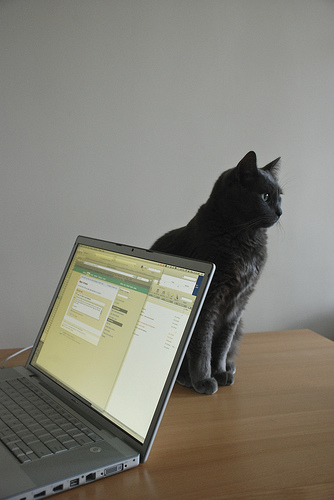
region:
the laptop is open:
[38, 257, 175, 489]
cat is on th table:
[176, 173, 291, 368]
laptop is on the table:
[48, 251, 205, 468]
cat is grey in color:
[194, 105, 275, 401]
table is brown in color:
[235, 372, 298, 439]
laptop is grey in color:
[23, 354, 127, 498]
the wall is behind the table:
[12, 71, 245, 331]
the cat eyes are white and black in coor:
[253, 187, 300, 207]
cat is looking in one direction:
[193, 147, 292, 343]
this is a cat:
[147, 150, 303, 412]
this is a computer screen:
[48, 244, 209, 434]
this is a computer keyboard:
[0, 383, 108, 461]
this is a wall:
[9, 7, 333, 330]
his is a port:
[86, 474, 97, 479]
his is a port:
[70, 479, 80, 485]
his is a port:
[51, 480, 68, 492]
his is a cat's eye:
[257, 190, 279, 207]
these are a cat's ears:
[238, 148, 295, 176]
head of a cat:
[213, 140, 307, 237]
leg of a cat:
[191, 308, 219, 386]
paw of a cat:
[187, 373, 226, 396]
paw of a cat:
[216, 364, 243, 389]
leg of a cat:
[206, 304, 251, 367]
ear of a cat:
[229, 131, 265, 178]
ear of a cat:
[264, 150, 290, 181]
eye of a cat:
[259, 187, 271, 202]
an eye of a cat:
[261, 190, 274, 200]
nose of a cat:
[268, 200, 287, 220]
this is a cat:
[181, 154, 289, 247]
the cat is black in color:
[217, 205, 248, 236]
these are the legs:
[197, 324, 231, 381]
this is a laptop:
[19, 309, 165, 455]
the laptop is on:
[64, 285, 166, 381]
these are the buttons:
[12, 395, 59, 447]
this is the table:
[221, 410, 305, 498]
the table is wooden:
[267, 374, 326, 446]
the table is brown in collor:
[229, 418, 308, 495]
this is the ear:
[239, 148, 257, 170]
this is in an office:
[10, 67, 290, 356]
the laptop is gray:
[22, 344, 109, 479]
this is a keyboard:
[3, 380, 81, 459]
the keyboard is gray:
[10, 385, 93, 479]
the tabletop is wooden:
[196, 416, 300, 498]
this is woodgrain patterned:
[214, 409, 333, 494]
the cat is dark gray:
[185, 157, 304, 334]